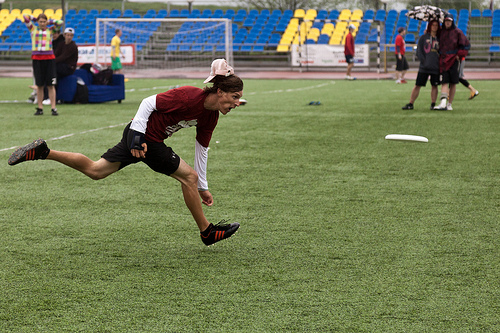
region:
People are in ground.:
[16, 20, 479, 252]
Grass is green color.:
[313, 191, 450, 296]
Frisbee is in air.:
[373, 128, 456, 151]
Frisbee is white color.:
[369, 126, 455, 167]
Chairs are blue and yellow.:
[206, 16, 358, 59]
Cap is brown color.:
[200, 56, 245, 94]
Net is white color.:
[90, 6, 248, 92]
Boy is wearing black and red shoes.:
[7, 135, 242, 269]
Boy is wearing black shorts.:
[98, 125, 206, 194]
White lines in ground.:
[17, 121, 121, 202]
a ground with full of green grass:
[278, 148, 447, 308]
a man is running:
[6, 48, 267, 238]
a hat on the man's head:
[196, 57, 250, 87]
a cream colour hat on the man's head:
[206, 56, 239, 85]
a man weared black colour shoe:
[187, 221, 251, 247]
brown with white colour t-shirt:
[129, 84, 214, 201]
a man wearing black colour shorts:
[118, 118, 180, 178]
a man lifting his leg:
[11, 136, 131, 181]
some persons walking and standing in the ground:
[345, 17, 481, 128]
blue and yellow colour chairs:
[258, 11, 420, 44]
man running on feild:
[12, 59, 243, 244]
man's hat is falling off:
[200, 60, 247, 110]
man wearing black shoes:
[9, 67, 243, 251]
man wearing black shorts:
[20, 68, 243, 244]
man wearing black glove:
[9, 70, 249, 244]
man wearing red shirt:
[17, 72, 244, 246]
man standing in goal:
[105, 29, 125, 71]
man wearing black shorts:
[340, 26, 356, 77]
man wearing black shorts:
[22, 14, 59, 119]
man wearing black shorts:
[443, 18, 470, 108]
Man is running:
[7, 71, 248, 248]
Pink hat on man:
[200, 55, 235, 84]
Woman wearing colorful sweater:
[19, 7, 66, 118]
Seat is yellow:
[292, 6, 304, 19]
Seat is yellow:
[43, 5, 53, 16]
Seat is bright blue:
[273, 22, 286, 32]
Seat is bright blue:
[489, 42, 499, 53]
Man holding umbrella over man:
[435, 12, 469, 113]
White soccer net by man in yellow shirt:
[93, 17, 236, 77]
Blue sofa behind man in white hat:
[55, 64, 129, 104]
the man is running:
[17, 14, 268, 238]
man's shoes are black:
[3, 122, 230, 243]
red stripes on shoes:
[205, 226, 235, 248]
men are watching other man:
[12, 2, 494, 101]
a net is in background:
[87, 9, 261, 86]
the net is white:
[82, 11, 259, 91]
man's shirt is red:
[121, 81, 238, 156]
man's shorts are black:
[98, 107, 188, 182]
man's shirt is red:
[380, 32, 411, 59]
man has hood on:
[440, 5, 460, 37]